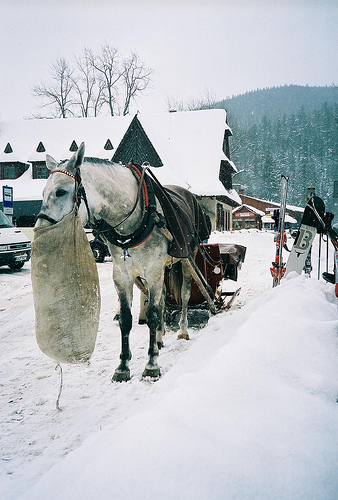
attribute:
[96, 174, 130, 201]
fur — white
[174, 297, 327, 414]
snow — cold, wet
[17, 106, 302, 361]
horse — ears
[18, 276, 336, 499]
snow — piled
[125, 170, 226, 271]
blanket — black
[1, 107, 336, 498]
snow — white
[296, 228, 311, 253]
letter — large, silver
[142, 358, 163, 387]
hoof — black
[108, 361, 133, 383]
hoof — black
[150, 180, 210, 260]
blanket — black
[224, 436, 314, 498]
snow — white, smooth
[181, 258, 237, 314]
sleigh — brown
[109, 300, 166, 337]
knees — blackened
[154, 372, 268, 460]
snow — white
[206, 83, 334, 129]
mountains — very high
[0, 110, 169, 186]
roof — triangular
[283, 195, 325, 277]
snowboard — black, white, leaning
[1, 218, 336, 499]
street — snowy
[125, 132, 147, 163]
designs — small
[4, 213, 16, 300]
van — white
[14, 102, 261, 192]
roof — snow covered